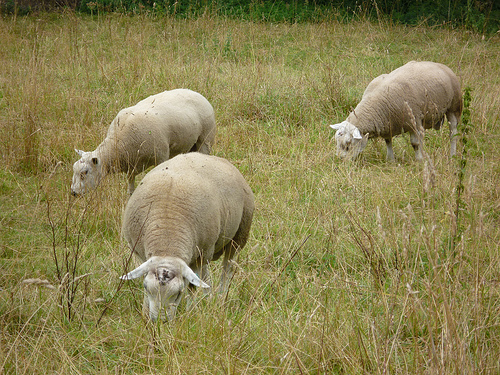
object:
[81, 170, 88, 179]
eye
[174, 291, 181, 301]
eye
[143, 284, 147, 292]
eye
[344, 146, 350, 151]
eye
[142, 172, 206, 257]
fleece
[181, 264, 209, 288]
ear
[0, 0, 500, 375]
field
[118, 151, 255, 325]
sheep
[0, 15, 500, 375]
pasture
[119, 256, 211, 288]
ears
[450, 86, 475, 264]
plant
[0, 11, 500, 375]
ground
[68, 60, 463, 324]
sheep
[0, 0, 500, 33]
green grass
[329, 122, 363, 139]
ears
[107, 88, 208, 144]
body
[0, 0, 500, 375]
grass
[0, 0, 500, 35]
trees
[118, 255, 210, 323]
head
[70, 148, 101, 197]
head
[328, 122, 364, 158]
head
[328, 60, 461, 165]
sheep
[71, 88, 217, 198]
sheep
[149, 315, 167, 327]
nose